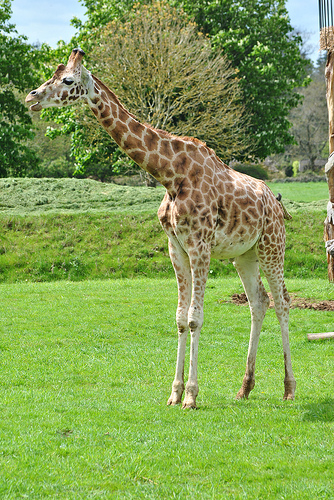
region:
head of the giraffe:
[14, 47, 110, 132]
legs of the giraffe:
[148, 324, 306, 423]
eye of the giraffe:
[54, 67, 87, 93]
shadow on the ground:
[299, 384, 332, 449]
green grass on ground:
[76, 407, 143, 455]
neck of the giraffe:
[92, 79, 202, 204]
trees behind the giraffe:
[129, 11, 282, 103]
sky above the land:
[15, 4, 67, 40]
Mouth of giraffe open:
[24, 99, 35, 107]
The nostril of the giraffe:
[31, 91, 35, 93]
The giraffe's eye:
[65, 81, 72, 84]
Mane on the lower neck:
[189, 137, 194, 141]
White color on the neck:
[89, 90, 92, 96]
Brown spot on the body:
[149, 137, 155, 145]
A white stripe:
[158, 142, 159, 148]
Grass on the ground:
[47, 301, 124, 337]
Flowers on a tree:
[147, 7, 165, 17]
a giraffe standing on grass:
[21, 44, 315, 411]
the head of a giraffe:
[15, 43, 95, 121]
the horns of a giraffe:
[66, 45, 87, 65]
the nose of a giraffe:
[22, 84, 49, 101]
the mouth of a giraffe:
[25, 98, 44, 111]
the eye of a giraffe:
[61, 77, 75, 90]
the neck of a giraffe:
[91, 70, 179, 192]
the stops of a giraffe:
[189, 180, 251, 237]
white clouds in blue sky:
[19, 8, 59, 38]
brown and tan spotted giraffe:
[18, 46, 305, 428]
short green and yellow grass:
[57, 317, 98, 351]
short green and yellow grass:
[202, 448, 236, 470]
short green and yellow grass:
[260, 432, 301, 467]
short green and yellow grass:
[137, 453, 163, 478]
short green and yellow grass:
[63, 389, 96, 428]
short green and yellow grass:
[68, 342, 102, 386]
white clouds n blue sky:
[33, 7, 58, 34]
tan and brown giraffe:
[18, 51, 308, 402]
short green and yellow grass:
[65, 437, 110, 468]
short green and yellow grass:
[210, 447, 249, 488]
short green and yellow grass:
[270, 437, 305, 483]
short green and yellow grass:
[87, 419, 114, 444]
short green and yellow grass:
[81, 447, 118, 484]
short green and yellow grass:
[67, 326, 107, 363]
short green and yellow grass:
[19, 330, 46, 363]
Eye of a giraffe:
[63, 77, 77, 89]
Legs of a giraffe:
[232, 263, 303, 405]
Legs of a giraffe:
[161, 251, 214, 410]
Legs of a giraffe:
[230, 263, 302, 399]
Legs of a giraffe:
[163, 255, 210, 406]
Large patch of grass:
[11, 306, 113, 401]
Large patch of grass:
[21, 391, 127, 474]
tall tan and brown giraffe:
[24, 46, 295, 409]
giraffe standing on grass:
[24, 49, 297, 409]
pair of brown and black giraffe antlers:
[68, 45, 84, 61]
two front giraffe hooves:
[164, 389, 199, 409]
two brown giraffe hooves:
[232, 376, 296, 400]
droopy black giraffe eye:
[62, 77, 75, 85]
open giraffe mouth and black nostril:
[23, 89, 43, 112]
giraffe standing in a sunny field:
[24, 46, 297, 409]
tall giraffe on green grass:
[25, 47, 298, 409]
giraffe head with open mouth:
[23, 45, 90, 111]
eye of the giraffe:
[60, 72, 75, 85]